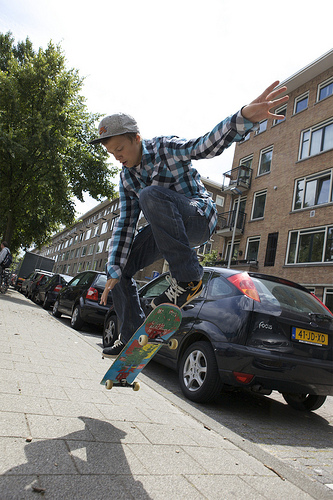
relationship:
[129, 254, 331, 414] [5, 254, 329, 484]
car on street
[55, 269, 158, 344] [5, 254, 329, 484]
car on street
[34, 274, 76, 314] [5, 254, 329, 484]
car on street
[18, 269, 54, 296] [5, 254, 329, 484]
car on street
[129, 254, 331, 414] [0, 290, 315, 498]
car along sidewalk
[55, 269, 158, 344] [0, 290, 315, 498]
car along sidewalk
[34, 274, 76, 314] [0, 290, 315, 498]
car along sidewalk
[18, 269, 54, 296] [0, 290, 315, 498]
car along sidewalk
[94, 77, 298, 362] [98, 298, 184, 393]
boy on skateboard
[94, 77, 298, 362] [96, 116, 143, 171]
boy has head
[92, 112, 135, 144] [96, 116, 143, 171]
hat on head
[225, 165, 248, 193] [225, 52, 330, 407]
balcony on building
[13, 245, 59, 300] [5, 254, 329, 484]
truck on street